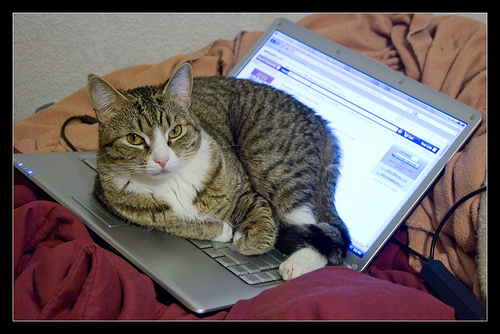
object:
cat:
[88, 63, 353, 283]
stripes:
[110, 202, 169, 215]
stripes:
[240, 194, 257, 218]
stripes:
[190, 157, 223, 204]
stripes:
[242, 91, 268, 139]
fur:
[251, 114, 311, 164]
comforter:
[13, 148, 454, 320]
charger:
[418, 260, 486, 319]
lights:
[24, 169, 34, 177]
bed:
[12, 13, 490, 320]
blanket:
[13, 13, 487, 297]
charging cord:
[59, 114, 97, 153]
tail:
[271, 162, 351, 267]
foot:
[279, 253, 305, 281]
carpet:
[13, 14, 488, 123]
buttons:
[240, 274, 261, 285]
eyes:
[121, 133, 149, 145]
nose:
[153, 148, 172, 167]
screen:
[233, 28, 467, 258]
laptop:
[13, 18, 481, 312]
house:
[11, 13, 487, 322]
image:
[87, 63, 352, 282]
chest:
[164, 177, 228, 223]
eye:
[165, 121, 184, 138]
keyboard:
[81, 157, 290, 286]